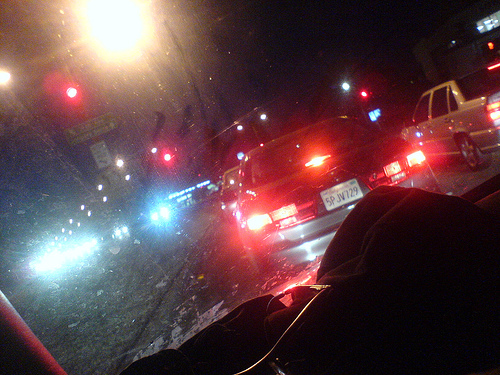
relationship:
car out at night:
[234, 119, 442, 274] [1, 0, 500, 374]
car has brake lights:
[234, 113, 442, 276] [247, 149, 428, 231]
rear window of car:
[250, 118, 383, 188] [234, 113, 442, 276]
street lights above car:
[63, 84, 371, 167] [234, 119, 442, 274]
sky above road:
[0, 0, 498, 197] [1, 148, 500, 374]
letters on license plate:
[325, 186, 360, 207] [319, 177, 364, 210]